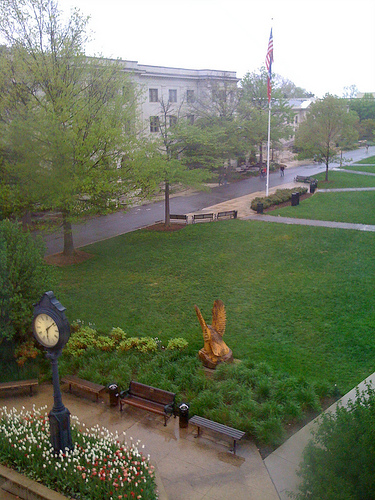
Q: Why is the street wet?
A: There was rain.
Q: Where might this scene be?
A: A college campus.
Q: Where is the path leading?
A: Park.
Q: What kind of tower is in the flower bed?
A: Clock.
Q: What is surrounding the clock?
A: Flowers.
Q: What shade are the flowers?
A: Pink and white.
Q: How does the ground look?
A: Wet.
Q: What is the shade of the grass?
A: Green.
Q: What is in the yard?
A: Flag.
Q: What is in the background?
A: Building.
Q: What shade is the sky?
A: Gray.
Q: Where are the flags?
A: On a flagpole.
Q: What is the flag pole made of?
A: Metal.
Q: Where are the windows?
A: On the building.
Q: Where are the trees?
A: On the lawn.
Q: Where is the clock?
A: On the black pole.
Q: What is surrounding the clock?
A: Flowers.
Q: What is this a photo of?
A: A park.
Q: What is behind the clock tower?
A: Park benches.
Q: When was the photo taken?
A: 6:10.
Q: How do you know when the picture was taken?
A: Clock.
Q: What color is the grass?
A: Green.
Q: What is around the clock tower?
A: Flowers.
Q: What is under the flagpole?
A: Benches.